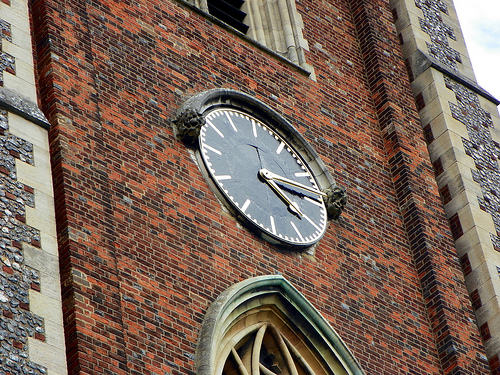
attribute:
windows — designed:
[168, 1, 370, 374]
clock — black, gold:
[197, 104, 329, 248]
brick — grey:
[312, 86, 389, 146]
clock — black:
[182, 97, 382, 280]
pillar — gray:
[390, 10, 497, 369]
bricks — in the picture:
[35, 124, 236, 358]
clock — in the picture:
[168, 86, 345, 244]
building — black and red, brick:
[33, 7, 498, 353]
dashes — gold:
[196, 106, 332, 251]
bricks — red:
[5, 5, 497, 373]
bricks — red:
[135, 201, 210, 263]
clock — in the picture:
[159, 62, 383, 316]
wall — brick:
[65, 15, 175, 114]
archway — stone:
[193, 271, 367, 372]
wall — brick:
[86, 0, 445, 373]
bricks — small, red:
[2, 265, 15, 274]